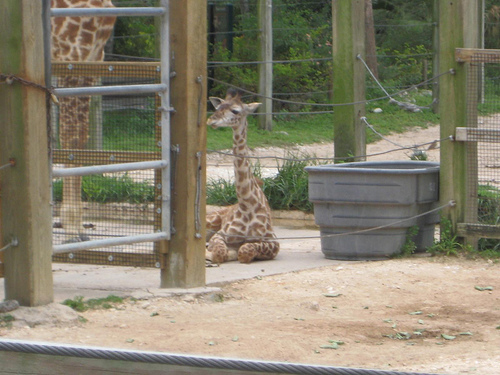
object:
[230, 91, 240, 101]
horn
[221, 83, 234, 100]
horn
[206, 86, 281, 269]
giraffe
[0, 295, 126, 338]
grass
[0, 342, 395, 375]
edge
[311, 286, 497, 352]
greens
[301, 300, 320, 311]
stone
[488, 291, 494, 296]
stone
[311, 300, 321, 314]
stone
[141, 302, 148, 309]
stone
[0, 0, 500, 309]
fence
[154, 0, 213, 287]
post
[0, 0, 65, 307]
post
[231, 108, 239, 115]
eye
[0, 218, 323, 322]
concrete floor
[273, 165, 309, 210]
leaves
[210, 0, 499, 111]
green leaves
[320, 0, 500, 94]
trees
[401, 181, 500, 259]
weeds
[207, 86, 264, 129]
head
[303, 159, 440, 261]
bin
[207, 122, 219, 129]
mouth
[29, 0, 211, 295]
gate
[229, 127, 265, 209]
neck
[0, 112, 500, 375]
dirt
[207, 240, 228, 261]
knee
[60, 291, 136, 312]
weed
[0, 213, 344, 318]
cement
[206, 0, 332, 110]
tree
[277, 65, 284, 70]
leaf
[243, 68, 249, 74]
leaf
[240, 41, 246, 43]
leaf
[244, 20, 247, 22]
leaf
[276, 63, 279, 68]
leaf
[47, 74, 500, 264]
grass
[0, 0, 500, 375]
enclosure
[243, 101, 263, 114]
ear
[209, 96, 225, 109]
ear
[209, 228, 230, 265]
leg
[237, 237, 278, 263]
leg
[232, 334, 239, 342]
leaf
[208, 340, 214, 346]
leaf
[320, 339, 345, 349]
leaf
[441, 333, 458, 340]
leaf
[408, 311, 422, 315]
leaf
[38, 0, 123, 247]
giraffe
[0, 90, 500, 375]
ground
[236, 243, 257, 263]
knee